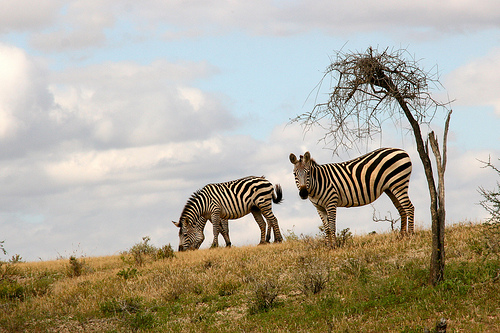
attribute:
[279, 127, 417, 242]
zebra — eating, looking, black, some, feeding, trio, bent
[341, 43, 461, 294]
tree — small, dead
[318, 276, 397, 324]
grass — green, short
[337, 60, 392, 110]
branches — small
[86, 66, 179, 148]
clouds — white, thick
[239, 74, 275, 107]
sky — blue, grey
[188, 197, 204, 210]
fur — black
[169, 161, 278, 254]
zebra — eating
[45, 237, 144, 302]
hill — grassy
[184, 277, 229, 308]
shrub — small